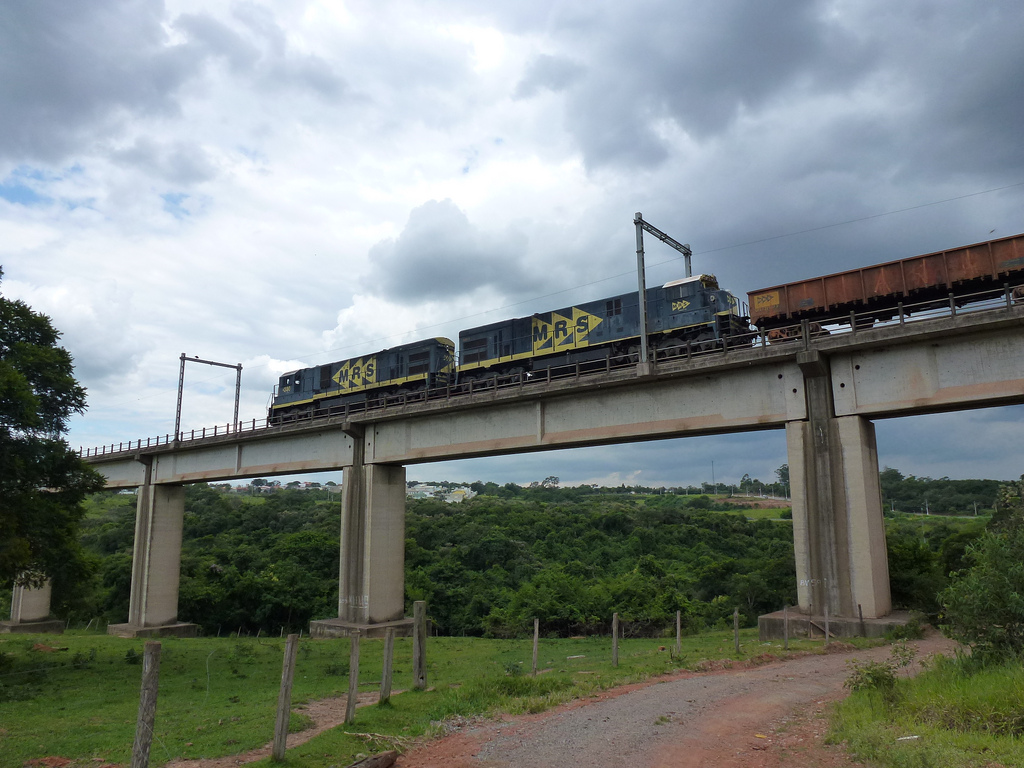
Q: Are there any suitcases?
A: No, there are no suitcases.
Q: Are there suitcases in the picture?
A: No, there are no suitcases.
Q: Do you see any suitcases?
A: No, there are no suitcases.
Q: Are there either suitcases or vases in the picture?
A: No, there are no suitcases or vases.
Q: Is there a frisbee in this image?
A: No, there are no frisbees.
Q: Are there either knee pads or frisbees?
A: No, there are no frisbees or knee pads.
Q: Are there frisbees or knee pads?
A: No, there are no frisbees or knee pads.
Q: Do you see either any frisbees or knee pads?
A: No, there are no frisbees or knee pads.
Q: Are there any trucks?
A: No, there are no trucks.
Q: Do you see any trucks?
A: No, there are no trucks.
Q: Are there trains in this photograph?
A: Yes, there is a train.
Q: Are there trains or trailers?
A: Yes, there is a train.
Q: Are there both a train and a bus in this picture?
A: No, there is a train but no buses.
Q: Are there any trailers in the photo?
A: No, there are no trailers.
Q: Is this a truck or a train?
A: This is a train.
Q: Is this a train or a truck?
A: This is a train.